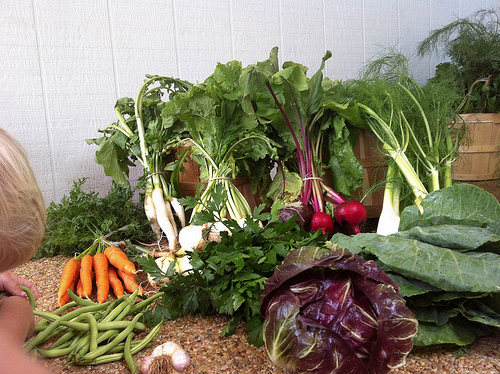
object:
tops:
[205, 45, 339, 161]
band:
[209, 177, 230, 181]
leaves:
[28, 176, 145, 261]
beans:
[14, 285, 166, 374]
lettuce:
[259, 245, 419, 374]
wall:
[0, 0, 497, 206]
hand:
[0, 270, 39, 301]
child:
[0, 122, 47, 374]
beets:
[237, 45, 369, 240]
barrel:
[175, 112, 499, 221]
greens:
[0, 12, 500, 374]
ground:
[18, 314, 500, 374]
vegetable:
[341, 37, 472, 236]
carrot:
[57, 245, 145, 307]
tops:
[165, 60, 283, 180]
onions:
[179, 226, 205, 253]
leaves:
[239, 65, 306, 152]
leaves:
[325, 182, 500, 348]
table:
[12, 257, 265, 374]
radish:
[310, 212, 334, 241]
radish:
[334, 200, 368, 235]